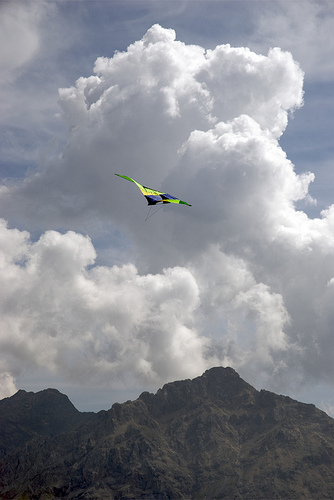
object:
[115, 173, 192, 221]
parasail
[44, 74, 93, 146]
sky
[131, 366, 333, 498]
area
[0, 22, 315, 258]
cloud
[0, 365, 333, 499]
mountain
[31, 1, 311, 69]
air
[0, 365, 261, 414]
peak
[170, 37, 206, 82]
light